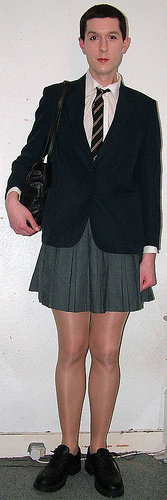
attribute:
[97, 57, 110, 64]
lipstick — red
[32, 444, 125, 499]
shoes — black, untied, men's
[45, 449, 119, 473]
shoe strings — black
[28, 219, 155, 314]
skirt — grey, gray, short, pleated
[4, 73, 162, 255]
jacket — black, blue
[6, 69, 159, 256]
shirt — white, button-down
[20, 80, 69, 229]
purse — black, leather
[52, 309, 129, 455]
stockings — beige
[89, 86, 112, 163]
tie — black, striped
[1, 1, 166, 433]
wall — white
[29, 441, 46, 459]
outlet — electrical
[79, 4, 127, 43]
hair — short, brown, close-cropped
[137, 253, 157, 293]
fist — clenched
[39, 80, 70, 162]
straps — long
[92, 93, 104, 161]
stripes — gray